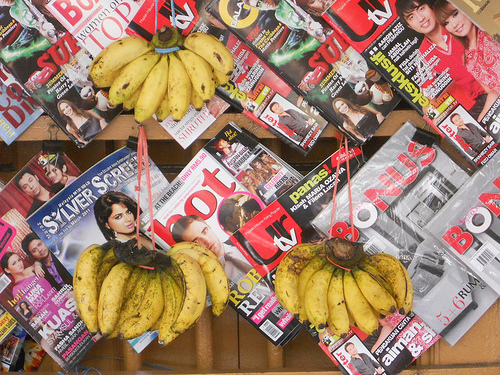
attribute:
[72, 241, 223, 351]
bananas — ripe, yellow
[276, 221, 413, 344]
bananas — ripe, yellow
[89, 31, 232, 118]
bananas — ripe, yellow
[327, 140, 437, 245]
word — bonus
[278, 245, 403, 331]
bananas — yellow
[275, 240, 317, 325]
banana — yellow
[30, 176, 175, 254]
magazine — titled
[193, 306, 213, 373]
dowel — wooden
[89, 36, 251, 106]
bananas — bunched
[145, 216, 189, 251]
lettering — red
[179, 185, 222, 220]
lettering — red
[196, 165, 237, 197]
lettering — red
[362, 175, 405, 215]
lettering — red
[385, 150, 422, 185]
lettering — red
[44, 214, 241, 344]
bananas — spotted, yellow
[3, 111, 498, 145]
board — wooden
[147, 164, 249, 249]
wor — bot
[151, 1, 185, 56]
string — attached, blue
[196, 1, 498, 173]
magazine — yellow, black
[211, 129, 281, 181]
magazine — blue, white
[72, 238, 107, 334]
banana — rot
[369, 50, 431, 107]
lettering — yellow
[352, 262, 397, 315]
banana — yellow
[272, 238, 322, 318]
banana — ripe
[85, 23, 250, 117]
yellow/ripe bananas — yellow, ripe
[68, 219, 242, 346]
yellow/ripe bananas — yellow, ripe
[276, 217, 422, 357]
yellow/ripe bananas — yellow, ripe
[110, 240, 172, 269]
tops — Black 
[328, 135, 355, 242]
string — red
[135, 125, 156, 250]
string — red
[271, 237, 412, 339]
bunch — ripe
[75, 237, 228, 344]
banana — yellow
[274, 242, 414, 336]
banana — yellow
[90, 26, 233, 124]
banana — yellow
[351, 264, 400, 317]
banana — ripe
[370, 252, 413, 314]
banana — ripe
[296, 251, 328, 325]
banana — ripe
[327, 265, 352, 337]
banana — ripe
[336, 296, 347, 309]
spot — brown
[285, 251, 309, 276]
spot — brown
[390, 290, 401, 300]
spot — brown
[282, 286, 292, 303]
spot — brown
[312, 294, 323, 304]
spot — brown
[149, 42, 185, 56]
tie — blue